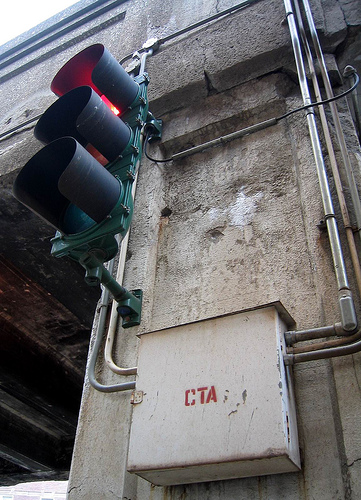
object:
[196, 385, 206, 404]
t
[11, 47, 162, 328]
traffic sign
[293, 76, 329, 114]
ground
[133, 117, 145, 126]
bolt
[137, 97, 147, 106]
bolt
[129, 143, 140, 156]
bolt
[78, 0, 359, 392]
pipes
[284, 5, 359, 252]
wire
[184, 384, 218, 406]
cta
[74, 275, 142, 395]
tubing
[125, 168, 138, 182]
bolt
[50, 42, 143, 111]
traffic light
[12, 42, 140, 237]
light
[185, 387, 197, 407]
c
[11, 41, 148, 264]
top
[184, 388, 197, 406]
letter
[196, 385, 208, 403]
letter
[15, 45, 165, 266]
signal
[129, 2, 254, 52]
metal tubing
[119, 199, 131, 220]
bolt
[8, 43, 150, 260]
box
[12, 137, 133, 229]
signal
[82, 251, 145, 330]
support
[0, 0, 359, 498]
building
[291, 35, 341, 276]
rods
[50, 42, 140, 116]
light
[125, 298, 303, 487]
box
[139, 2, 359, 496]
wall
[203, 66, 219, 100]
crack